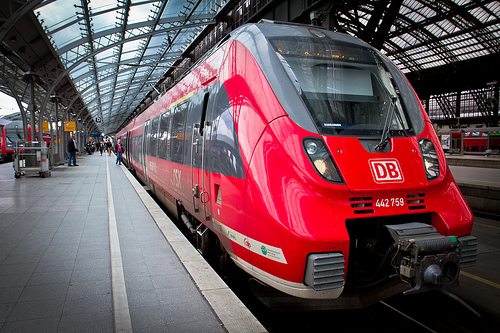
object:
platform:
[0, 129, 269, 333]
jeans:
[68, 151, 77, 165]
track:
[369, 297, 500, 331]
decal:
[368, 158, 405, 184]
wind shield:
[264, 31, 426, 140]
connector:
[400, 251, 462, 295]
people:
[66, 134, 79, 166]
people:
[99, 141, 104, 155]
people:
[106, 139, 113, 156]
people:
[94, 140, 99, 151]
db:
[373, 163, 399, 179]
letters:
[170, 168, 181, 188]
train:
[0, 110, 76, 164]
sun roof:
[0, 0, 500, 148]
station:
[0, 0, 500, 333]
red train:
[112, 19, 479, 312]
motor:
[385, 221, 478, 295]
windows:
[33, 2, 228, 134]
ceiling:
[0, 1, 499, 62]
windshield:
[251, 32, 424, 139]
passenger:
[115, 138, 125, 165]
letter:
[373, 163, 387, 178]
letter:
[385, 162, 399, 178]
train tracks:
[272, 292, 491, 333]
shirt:
[114, 143, 125, 152]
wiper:
[373, 73, 408, 151]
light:
[301, 135, 347, 185]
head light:
[417, 137, 442, 181]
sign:
[64, 121, 76, 131]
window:
[111, 97, 226, 160]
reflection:
[109, 22, 479, 300]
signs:
[38, 121, 50, 131]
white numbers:
[376, 198, 405, 208]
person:
[113, 136, 125, 169]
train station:
[0, 0, 500, 333]